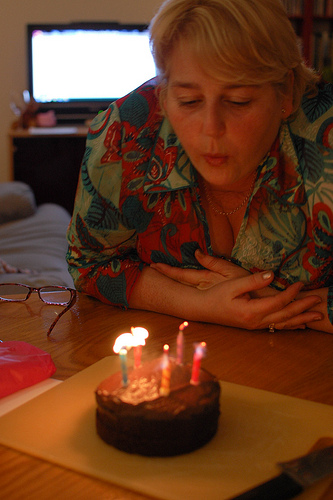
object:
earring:
[281, 109, 285, 113]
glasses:
[0, 282, 78, 337]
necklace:
[202, 168, 258, 216]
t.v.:
[25, 20, 157, 109]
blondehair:
[148, 0, 320, 118]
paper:
[0, 355, 333, 500]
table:
[0, 289, 333, 497]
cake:
[95, 358, 222, 457]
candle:
[189, 341, 206, 387]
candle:
[176, 321, 188, 364]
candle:
[159, 344, 172, 397]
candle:
[113, 332, 131, 388]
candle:
[132, 326, 149, 367]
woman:
[65, 0, 333, 332]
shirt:
[65, 74, 333, 326]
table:
[0, 315, 63, 337]